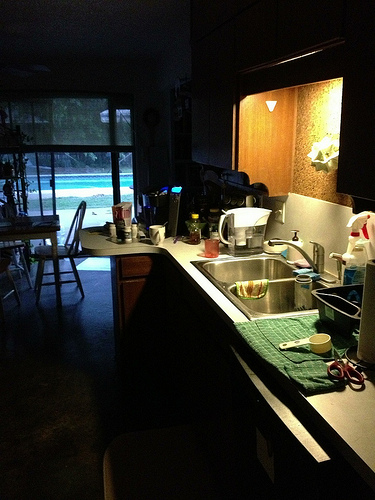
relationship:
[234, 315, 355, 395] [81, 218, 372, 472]
dish towel on counter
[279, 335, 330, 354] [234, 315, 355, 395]
measuring cup on dish towel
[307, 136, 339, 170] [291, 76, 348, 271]
light on wall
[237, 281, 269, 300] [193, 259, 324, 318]
rag on sink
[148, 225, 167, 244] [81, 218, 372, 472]
cup on counter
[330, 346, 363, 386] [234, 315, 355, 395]
scissors laying on dish towel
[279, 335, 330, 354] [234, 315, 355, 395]
measuring cup lying on dish towel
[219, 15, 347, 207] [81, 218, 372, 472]
water filter on counter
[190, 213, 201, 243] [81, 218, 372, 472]
bottle of honey sitting on counter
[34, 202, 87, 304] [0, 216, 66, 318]
chair sitting at table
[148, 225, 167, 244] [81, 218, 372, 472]
coffee cup sitting on counter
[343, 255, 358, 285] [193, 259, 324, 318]
dish detergent by sink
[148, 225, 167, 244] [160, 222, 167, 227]
cup with spoon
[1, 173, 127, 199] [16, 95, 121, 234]
pool viewed from he sliding door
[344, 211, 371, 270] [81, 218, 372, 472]
spray bottle on counter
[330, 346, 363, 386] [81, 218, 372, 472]
scissors on counter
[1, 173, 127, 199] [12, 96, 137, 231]
pool in backyard